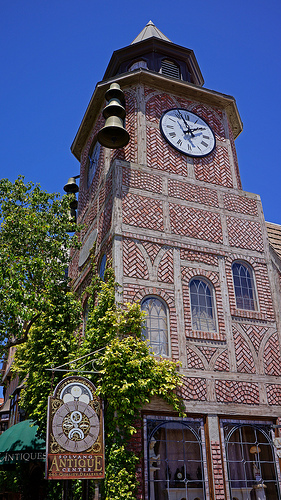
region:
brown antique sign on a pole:
[38, 369, 109, 483]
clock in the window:
[172, 466, 184, 480]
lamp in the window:
[243, 441, 262, 468]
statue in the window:
[148, 434, 161, 467]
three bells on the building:
[94, 78, 131, 151]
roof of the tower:
[137, 14, 175, 32]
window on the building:
[142, 413, 206, 499]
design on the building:
[216, 378, 258, 403]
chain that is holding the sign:
[46, 370, 56, 390]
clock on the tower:
[156, 98, 217, 161]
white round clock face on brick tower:
[160, 103, 216, 160]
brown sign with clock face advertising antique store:
[44, 373, 107, 476]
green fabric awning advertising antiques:
[2, 417, 59, 464]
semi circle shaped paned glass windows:
[147, 420, 202, 496]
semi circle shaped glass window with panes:
[225, 419, 277, 497]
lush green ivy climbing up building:
[8, 249, 193, 496]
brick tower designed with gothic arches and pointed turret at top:
[58, 17, 279, 487]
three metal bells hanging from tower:
[94, 83, 130, 156]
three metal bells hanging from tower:
[59, 173, 83, 232]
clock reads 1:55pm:
[155, 105, 216, 160]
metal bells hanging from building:
[96, 82, 129, 148]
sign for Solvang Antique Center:
[46, 374, 104, 479]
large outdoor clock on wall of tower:
[158, 107, 214, 157]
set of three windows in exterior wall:
[131, 252, 259, 358]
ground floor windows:
[139, 414, 278, 498]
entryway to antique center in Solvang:
[1, 417, 45, 498]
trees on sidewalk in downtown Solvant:
[0, 176, 186, 497]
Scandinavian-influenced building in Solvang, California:
[0, 14, 280, 498]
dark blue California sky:
[1, 2, 279, 221]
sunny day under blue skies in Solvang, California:
[1, 0, 279, 498]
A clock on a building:
[156, 103, 221, 161]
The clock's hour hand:
[171, 104, 195, 138]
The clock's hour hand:
[183, 123, 204, 136]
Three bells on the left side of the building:
[94, 80, 132, 151]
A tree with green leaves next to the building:
[0, 171, 192, 496]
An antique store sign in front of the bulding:
[44, 344, 107, 480]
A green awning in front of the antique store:
[0, 415, 45, 463]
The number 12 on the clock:
[183, 112, 191, 122]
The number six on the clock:
[186, 142, 192, 152]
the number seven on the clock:
[175, 138, 184, 148]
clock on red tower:
[150, 98, 216, 170]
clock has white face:
[155, 106, 209, 154]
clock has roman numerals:
[159, 111, 207, 153]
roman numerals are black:
[154, 108, 212, 156]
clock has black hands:
[156, 99, 208, 155]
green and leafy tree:
[8, 185, 156, 433]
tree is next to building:
[6, 183, 112, 406]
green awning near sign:
[6, 415, 38, 460]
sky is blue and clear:
[10, 18, 72, 141]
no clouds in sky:
[12, 23, 87, 145]